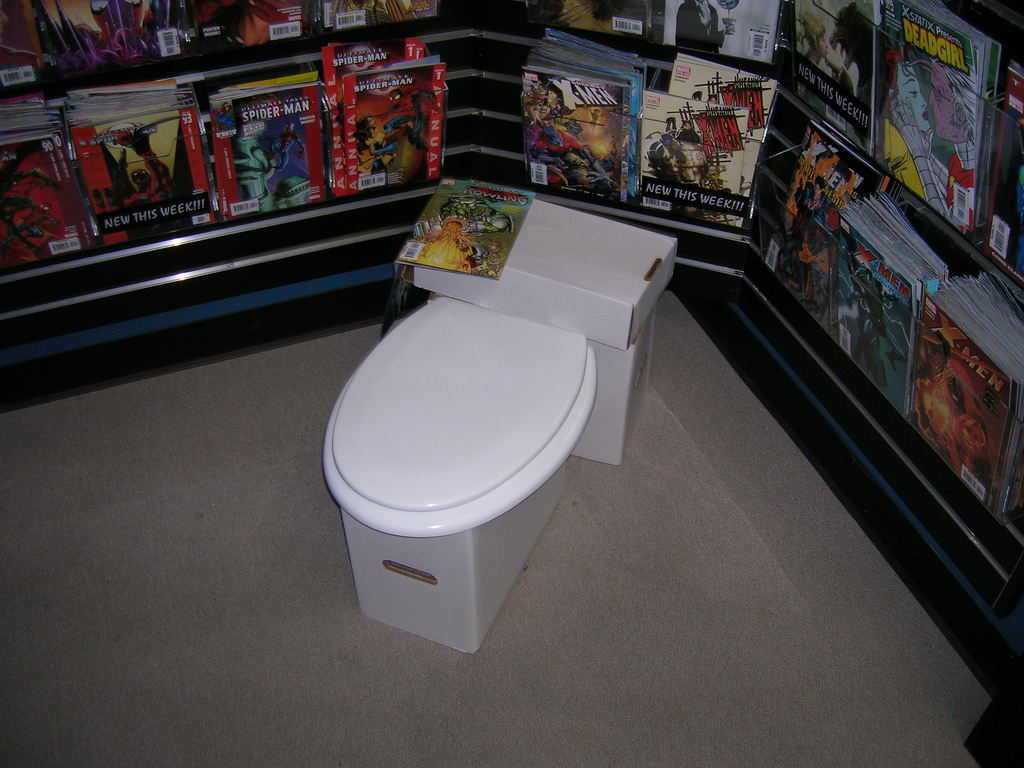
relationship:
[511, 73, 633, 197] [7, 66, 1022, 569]
comic on shelf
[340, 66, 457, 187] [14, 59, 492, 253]
comic on a shelf